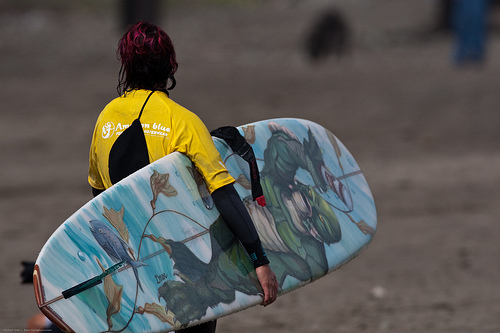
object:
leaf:
[102, 201, 137, 261]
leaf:
[96, 257, 124, 331]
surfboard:
[33, 116, 380, 331]